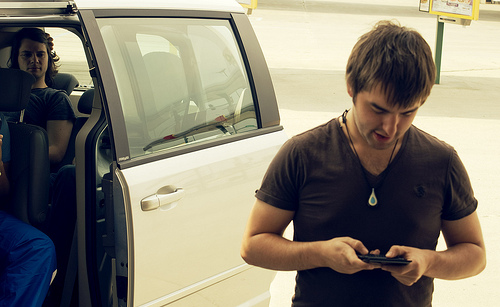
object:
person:
[359, 152, 466, 206]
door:
[0, 1, 136, 306]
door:
[70, 0, 285, 306]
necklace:
[342, 109, 399, 206]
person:
[0, 86, 61, 303]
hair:
[345, 19, 437, 111]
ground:
[245, 0, 500, 306]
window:
[75, 9, 279, 159]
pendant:
[368, 188, 378, 207]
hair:
[6, 27, 62, 84]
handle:
[141, 188, 184, 210]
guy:
[6, 27, 75, 160]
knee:
[0, 215, 57, 274]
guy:
[239, 18, 485, 307]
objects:
[410, 3, 484, 55]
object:
[418, 0, 479, 26]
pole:
[435, 22, 444, 85]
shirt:
[254, 109, 478, 306]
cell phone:
[356, 254, 412, 266]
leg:
[0, 213, 57, 307]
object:
[234, 0, 258, 9]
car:
[0, 0, 285, 307]